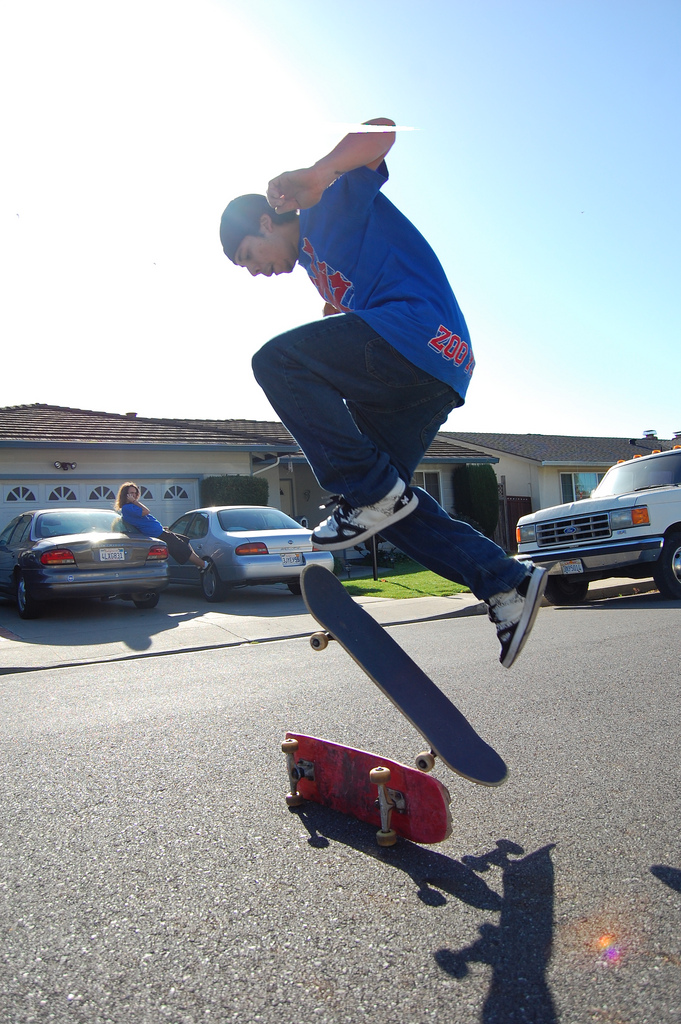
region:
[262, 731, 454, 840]
Red skateboard turn on the side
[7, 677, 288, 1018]
A street in front of a house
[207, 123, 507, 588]
A boy jumping on a skateboard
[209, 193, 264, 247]
A hat on a boy's head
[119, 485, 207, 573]
girl lend of a car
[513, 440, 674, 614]
truck sitting in front of house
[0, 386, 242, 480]
the roof of a house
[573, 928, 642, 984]
Orange and purple color on the street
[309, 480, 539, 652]
A boy white and blue shoes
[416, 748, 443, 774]
wheel on the vehicle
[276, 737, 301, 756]
wheel on the vehicle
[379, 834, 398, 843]
wheel on the vehicle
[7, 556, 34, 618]
wheel on the vehicle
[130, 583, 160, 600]
wheel on the vehicle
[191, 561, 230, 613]
wheel on the vehicle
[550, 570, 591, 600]
wheel on the vehicle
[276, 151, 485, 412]
THE GUY IS WEARING A BLUE SHIRT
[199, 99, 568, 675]
THE GUY IS DOING A TRICK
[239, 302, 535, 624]
THE BOY IS WEARING JEANS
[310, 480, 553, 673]
THE MAN IS WEARING TENNIS SHOES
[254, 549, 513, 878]
THE GUY HAS TWO SKATEBOARDS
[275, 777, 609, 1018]
THESE ARE SHADOWS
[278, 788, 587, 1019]
THE SHADOWS ARE ON THE STREET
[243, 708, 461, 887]
THE SKATEBOARD IS RED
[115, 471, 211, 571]
THE MAN IS LEANING ON THE CARS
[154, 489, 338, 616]
THE CAR IS SILVER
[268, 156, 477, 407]
THE GUY'S SHIRT HAS RED WRITING ON IT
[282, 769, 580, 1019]
THE SHADOW IS ON THE ROAD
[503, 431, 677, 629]
THE TRUCK IS WHITE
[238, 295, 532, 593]
THE GUY IS WEARING BLUE JEANS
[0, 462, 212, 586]
THE GARAGE DOOR IS WHITE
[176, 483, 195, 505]
a window on th ehouse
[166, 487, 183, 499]
a window on th ehouse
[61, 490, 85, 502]
a window on th ehouse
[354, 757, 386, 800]
a wheel on the skateboard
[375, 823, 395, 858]
a wheel on the skateboard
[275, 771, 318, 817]
a wheel on the skateboard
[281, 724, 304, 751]
a wheel on the skateboard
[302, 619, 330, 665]
a wheel on the skateboard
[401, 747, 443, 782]
a wheel on the skateboard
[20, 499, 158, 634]
a car in the driveway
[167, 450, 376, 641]
a car in the driveway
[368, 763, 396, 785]
Wheel on a skateboard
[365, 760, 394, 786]
White wheel of a skateboard